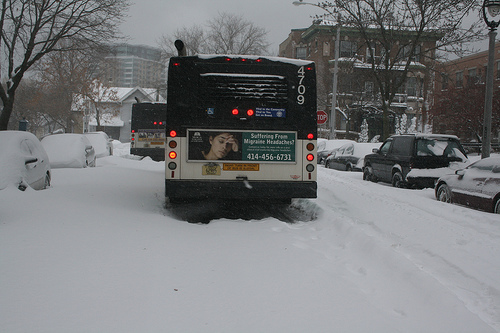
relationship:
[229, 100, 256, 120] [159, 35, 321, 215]
lights on bus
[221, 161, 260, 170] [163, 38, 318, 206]
license plate on bus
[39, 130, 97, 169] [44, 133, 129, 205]
car parked in snow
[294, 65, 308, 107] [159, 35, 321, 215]
numbers on back bus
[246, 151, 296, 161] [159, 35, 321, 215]
numbers on back bus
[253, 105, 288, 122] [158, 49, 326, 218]
sign on bus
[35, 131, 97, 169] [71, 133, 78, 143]
car covered in snow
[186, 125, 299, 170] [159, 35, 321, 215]
sign on bus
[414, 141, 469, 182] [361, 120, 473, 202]
snow on car